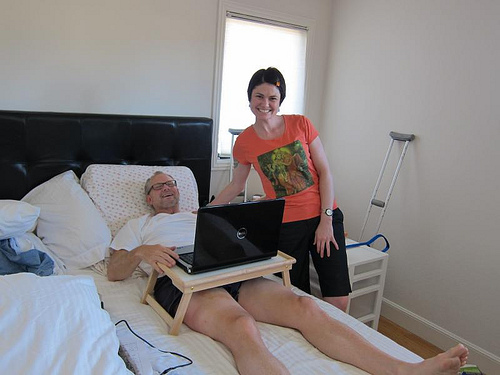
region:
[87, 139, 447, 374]
man laying in bed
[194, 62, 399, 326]
woman standing beside the bed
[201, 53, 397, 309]
woman with short dark hair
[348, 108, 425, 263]
silver crutch leaning against the wall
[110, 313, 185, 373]
black cord on the bed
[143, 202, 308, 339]
black laptop on a tray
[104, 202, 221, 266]
bright white tee shirt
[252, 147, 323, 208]
design on the shirt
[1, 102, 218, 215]
large black bedframe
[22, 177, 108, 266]
white pillow propped up on the bed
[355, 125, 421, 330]
metal crutch with gray pads leaning against wall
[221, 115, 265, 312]
metal crutch with gray pads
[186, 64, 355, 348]
woman in orange shirt and black shorts standing next to bed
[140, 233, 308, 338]
light brown wooden bed desk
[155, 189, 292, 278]
rectangular black laptop computer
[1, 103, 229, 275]
black leather headboard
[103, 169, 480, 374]
man in white shirt lying in bed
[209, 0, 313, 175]
window with bright white light shining through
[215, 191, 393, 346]
white nightstand next to bed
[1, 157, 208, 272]
large thick pillows on bed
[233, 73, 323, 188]
this is a lady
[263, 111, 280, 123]
the lady is light skinned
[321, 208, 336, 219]
this is a watch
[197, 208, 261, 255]
this is a laptop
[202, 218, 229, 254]
the laptop is black in color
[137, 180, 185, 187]
this is a spectacle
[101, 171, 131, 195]
this is a pillow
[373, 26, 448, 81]
this is the wall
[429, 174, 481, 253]
the wall is white in color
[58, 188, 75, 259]
the pillow is white in color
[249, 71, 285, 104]
woman has brown hair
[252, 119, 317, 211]
woman has orange shirt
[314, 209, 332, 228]
woman wears wrist watch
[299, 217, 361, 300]
woman has black shorts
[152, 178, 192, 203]
man is wearing glasses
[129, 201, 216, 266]
man has white shirt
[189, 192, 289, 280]
man has black laptop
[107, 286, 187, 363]
black cord next to laptop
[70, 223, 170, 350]
white sheet on bed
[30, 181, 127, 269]
white pillows next to man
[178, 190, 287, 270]
this is the laptop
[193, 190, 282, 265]
the laptop is black in color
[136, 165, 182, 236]
this is a man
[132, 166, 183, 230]
the man is lying on the bed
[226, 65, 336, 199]
this is a woman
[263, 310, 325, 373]
the legs are apart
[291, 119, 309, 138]
the shirt is orange in color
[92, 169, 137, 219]
his head on the pilow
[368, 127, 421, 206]
this is the cratches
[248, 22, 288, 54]
the window is closed